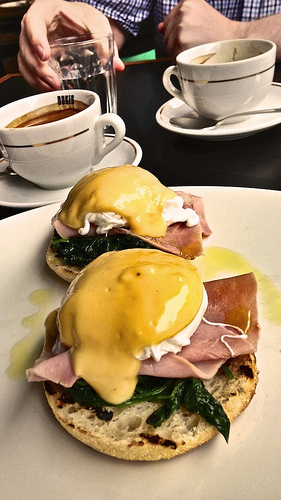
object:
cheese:
[59, 162, 177, 237]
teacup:
[160, 38, 276, 123]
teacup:
[0, 89, 126, 188]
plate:
[154, 79, 281, 135]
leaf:
[49, 229, 154, 267]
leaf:
[184, 379, 229, 442]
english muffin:
[46, 231, 86, 283]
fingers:
[19, 13, 62, 91]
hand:
[17, 0, 126, 94]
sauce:
[225, 302, 254, 333]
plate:
[0, 184, 281, 500]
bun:
[43, 352, 259, 462]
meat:
[175, 271, 260, 363]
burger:
[25, 246, 259, 461]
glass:
[48, 33, 117, 135]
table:
[0, 59, 281, 500]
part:
[139, 432, 178, 455]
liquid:
[61, 72, 116, 116]